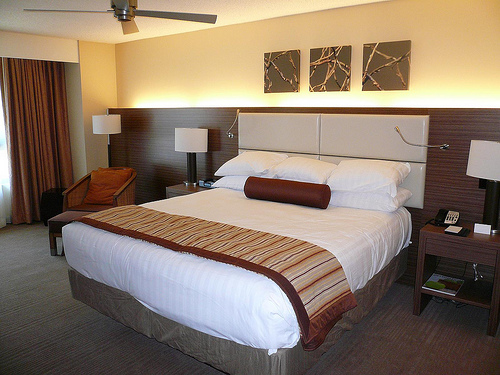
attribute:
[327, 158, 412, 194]
pillow — white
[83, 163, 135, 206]
pillows — orange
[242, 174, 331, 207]
pillow — brown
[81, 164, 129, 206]
pillow — brown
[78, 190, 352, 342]
blanket — MULTI COLORED 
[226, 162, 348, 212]
roll — red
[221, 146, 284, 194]
pillow — white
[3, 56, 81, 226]
curtains — Brown 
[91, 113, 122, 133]
shade — white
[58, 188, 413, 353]
sheets — white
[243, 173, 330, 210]
pillow — red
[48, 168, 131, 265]
chair — SMALL 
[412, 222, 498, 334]
table — wooden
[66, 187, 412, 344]
sheet — white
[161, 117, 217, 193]
lamp — black, white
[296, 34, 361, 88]
picture — square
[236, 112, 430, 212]
headboard — white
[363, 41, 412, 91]
picture — square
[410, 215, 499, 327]
bedside table — SMALL 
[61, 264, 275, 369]
skirting — gray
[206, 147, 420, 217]
pillows — white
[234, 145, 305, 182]
pillow — white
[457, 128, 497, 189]
shade — white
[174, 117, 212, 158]
shade — white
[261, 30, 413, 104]
pictures — decorative  